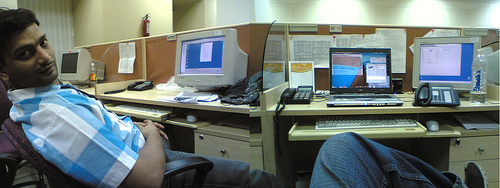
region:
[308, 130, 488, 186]
a person sitting in the office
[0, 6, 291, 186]
a person sitting in the office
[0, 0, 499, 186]
the interior of an office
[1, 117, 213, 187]
an office chair with purple back rest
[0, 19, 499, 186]
a row of office desks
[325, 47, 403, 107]
a laptop on a desk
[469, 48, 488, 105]
a water bottle on a desk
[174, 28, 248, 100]
a computer monitor on a desk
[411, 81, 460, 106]
a telephone on a desk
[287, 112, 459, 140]
a sliding tray under a desk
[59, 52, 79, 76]
the computer screen on a computer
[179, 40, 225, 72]
the computer screen on a computer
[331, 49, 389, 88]
the computer screen on a computer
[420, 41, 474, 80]
the computer screen on a computer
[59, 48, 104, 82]
an old bulky computer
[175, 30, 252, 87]
an old bulky computer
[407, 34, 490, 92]
an old bulky computer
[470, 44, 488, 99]
a clear water bottle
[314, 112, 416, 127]
the leg of a person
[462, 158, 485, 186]
the shoe of a person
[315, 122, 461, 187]
Knee on a person wearing jeans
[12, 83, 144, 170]
Blue and white checked shirt on a man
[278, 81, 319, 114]
Black phone on a desk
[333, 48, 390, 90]
Black computer moniter on a desk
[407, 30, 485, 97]
Gray computer moniter on a desk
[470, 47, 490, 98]
Water bottle on a desk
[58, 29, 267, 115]
Desk with computers on it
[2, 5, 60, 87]
Dark hair on a man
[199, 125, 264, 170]
Drawer on a desk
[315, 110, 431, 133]
Keyboard on a desk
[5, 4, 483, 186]
Man sitting in a chair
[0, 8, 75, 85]
Man looking at the camera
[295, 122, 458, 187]
Man wearing blue jeans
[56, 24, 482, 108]
Four computers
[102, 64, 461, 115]
Four phones on the desk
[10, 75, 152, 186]
Blue and white collared shirt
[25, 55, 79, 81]
Man has facial hair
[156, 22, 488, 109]
These three computers are turned on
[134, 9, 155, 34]
Fire extinguisher on the wall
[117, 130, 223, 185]
Right arm on the armrest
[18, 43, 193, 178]
Man sitting back in the chair.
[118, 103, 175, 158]
The man hands on his stomach.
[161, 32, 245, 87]
The monitor on the desk.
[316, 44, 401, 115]
A laptop on the desk.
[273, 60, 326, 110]
Black telephone on the desk.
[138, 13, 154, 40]
A fire extinguisher on the wall.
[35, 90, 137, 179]
The shirt is blue and white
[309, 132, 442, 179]
A person with legs crossed.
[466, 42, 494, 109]
A water bottle on the desk.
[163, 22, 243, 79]
The monitor is turned on.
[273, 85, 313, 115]
the phone is black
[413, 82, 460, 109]
the phone is black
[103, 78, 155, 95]
the phone is black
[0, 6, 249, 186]
the man is sitting down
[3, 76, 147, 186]
the shirt is blue and white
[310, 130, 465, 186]
the jeans are blue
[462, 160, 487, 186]
the shoe is black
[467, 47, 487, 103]
the plastic bottle is clear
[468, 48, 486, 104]
the liquid in the bottle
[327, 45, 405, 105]
the laptop is turned on